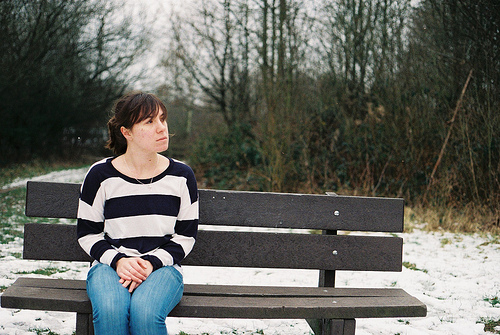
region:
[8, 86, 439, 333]
woman sits on a bench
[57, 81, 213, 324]
woman face to the right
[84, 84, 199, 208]
woman combs in a pony tail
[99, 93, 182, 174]
woman has pimples on his face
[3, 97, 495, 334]
a field covered with snow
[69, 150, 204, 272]
a white and black sweater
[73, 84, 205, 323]
woman holds hands on her lap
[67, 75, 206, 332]
woman wears blue jean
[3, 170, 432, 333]
a bench of wood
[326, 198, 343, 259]
bolts on a bench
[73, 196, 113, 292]
she's sitting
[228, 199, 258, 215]
the bench is weathered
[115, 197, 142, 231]
the shirt has stripes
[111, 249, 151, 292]
her hands are in her lap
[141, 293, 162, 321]
the pants are blue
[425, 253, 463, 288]
snow is on the ground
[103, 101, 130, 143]
her hair is in a ponytail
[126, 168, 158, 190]
she's wearing a necklace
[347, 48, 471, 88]
the row of trees are green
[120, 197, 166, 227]
her shirt is blue and white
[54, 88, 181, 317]
a woman sittiing down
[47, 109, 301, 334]
a woman sitting outside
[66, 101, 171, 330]
a woman sitting on a bench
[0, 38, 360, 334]
a woman in snowy weather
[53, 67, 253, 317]
a woman with brown hair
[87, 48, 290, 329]
a woman with hair up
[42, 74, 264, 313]
a woman with brown hair up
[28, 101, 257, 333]
a woman wearing a long sleeve shirt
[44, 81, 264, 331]
a woman wearing a striped shirt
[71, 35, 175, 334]
a woman wearing jeans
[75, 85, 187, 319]
woman sitting on bench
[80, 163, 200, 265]
black and white shirt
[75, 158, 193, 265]
black and white stripes on shirt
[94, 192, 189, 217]
black stripe on shirt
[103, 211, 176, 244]
white stripe on shirt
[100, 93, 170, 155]
brown hair on face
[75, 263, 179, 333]
blue jeans on woman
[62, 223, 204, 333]
woman wearing blue jeans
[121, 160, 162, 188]
small necklace on woman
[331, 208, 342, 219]
silver bolt from bench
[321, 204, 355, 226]
silver bolt in gray bench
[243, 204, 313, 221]
gray color on the bench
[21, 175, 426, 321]
large gray bench on the ground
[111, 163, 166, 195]
dainty silver necklace around neck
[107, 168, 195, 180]
blue lines on sweater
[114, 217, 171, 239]
white stripes on sweater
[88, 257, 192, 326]
woman wearing blue jeans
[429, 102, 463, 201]
long branch in the woods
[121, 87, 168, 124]
black bangs in woman's face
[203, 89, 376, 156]
trees in the woods